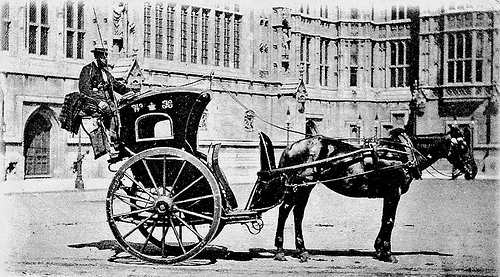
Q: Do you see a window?
A: Yes, there is a window.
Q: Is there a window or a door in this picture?
A: Yes, there is a window.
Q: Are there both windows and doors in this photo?
A: Yes, there are both a window and a door.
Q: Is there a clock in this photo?
A: No, there are no clocks.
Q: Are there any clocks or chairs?
A: No, there are no clocks or chairs.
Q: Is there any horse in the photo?
A: Yes, there is a horse.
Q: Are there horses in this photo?
A: Yes, there is a horse.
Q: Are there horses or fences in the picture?
A: Yes, there is a horse.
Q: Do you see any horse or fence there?
A: Yes, there is a horse.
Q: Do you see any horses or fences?
A: Yes, there is a horse.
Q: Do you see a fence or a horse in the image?
A: Yes, there is a horse.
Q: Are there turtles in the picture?
A: No, there are no turtles.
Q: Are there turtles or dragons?
A: No, there are no turtles or dragons.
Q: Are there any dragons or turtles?
A: No, there are no turtles or dragons.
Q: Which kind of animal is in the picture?
A: The animal is a horse.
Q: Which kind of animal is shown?
A: The animal is a horse.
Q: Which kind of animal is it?
A: The animal is a horse.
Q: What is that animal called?
A: This is a horse.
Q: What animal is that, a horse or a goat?
A: This is a horse.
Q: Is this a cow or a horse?
A: This is a horse.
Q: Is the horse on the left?
A: No, the horse is on the right of the image.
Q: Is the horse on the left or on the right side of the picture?
A: The horse is on the right of the image.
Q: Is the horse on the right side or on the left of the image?
A: The horse is on the right of the image.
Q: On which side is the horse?
A: The horse is on the right of the image.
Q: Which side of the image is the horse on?
A: The horse is on the right of the image.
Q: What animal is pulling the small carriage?
A: The horse is pulling the carriage.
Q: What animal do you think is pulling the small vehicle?
A: The horse is pulling the carriage.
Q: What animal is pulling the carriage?
A: The horse is pulling the carriage.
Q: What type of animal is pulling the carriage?
A: The animal is a horse.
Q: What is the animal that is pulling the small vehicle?
A: The animal is a horse.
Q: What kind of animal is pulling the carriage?
A: The animal is a horse.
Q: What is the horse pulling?
A: The horse is pulling the carriage.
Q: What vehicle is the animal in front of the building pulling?
A: The horse is pulling the carriage.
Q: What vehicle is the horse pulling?
A: The horse is pulling the carriage.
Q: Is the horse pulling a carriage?
A: Yes, the horse is pulling a carriage.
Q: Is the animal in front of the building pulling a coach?
A: No, the horse is pulling a carriage.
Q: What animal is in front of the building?
A: The horse is in front of the building.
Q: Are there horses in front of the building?
A: Yes, there is a horse in front of the building.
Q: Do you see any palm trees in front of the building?
A: No, there is a horse in front of the building.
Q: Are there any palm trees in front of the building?
A: No, there is a horse in front of the building.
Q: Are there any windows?
A: Yes, there is a window.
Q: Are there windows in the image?
A: Yes, there is a window.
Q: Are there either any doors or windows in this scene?
A: Yes, there is a window.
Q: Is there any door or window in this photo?
A: Yes, there is a window.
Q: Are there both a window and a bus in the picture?
A: No, there is a window but no buses.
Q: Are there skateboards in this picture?
A: No, there are no skateboards.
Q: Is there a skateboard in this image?
A: No, there are no skateboards.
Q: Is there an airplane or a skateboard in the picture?
A: No, there are no skateboards or airplanes.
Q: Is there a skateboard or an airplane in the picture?
A: No, there are no skateboards or airplanes.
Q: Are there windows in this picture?
A: Yes, there is a window.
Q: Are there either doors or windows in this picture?
A: Yes, there is a window.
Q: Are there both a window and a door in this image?
A: Yes, there are both a window and a door.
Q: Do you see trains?
A: No, there are no trains.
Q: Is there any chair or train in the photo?
A: No, there are no trains or chairs.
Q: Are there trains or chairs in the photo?
A: No, there are no trains or chairs.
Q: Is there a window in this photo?
A: Yes, there is a window.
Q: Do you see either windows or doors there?
A: Yes, there is a window.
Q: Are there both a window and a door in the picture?
A: Yes, there are both a window and a door.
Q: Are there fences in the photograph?
A: No, there are no fences.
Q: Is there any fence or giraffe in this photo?
A: No, there are no fences or giraffes.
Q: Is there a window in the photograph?
A: Yes, there is a window.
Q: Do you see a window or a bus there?
A: Yes, there is a window.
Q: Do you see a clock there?
A: No, there are no clocks.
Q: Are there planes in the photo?
A: No, there are no planes.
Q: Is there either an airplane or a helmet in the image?
A: No, there are no airplanes or helmets.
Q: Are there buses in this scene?
A: No, there are no buses.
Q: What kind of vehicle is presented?
A: The vehicle is a carriage.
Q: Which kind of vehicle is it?
A: The vehicle is a carriage.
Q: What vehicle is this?
A: This is a carriage.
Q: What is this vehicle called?
A: This is a carriage.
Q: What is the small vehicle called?
A: The vehicle is a carriage.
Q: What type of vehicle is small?
A: The vehicle is a carriage.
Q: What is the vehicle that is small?
A: The vehicle is a carriage.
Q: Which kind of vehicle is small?
A: The vehicle is a carriage.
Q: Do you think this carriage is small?
A: Yes, the carriage is small.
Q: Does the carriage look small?
A: Yes, the carriage is small.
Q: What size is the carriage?
A: The carriage is small.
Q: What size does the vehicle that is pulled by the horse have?
A: The carriage has small size.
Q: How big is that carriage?
A: The carriage is small.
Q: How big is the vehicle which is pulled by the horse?
A: The carriage is small.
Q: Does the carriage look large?
A: No, the carriage is small.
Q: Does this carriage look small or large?
A: The carriage is small.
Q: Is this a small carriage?
A: Yes, this is a small carriage.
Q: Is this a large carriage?
A: No, this is a small carriage.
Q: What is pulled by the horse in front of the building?
A: The carriage is pulled by the horse.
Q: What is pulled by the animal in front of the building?
A: The carriage is pulled by the horse.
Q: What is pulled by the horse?
A: The carriage is pulled by the horse.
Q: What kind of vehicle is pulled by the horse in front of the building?
A: The vehicle is a carriage.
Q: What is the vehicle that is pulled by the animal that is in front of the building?
A: The vehicle is a carriage.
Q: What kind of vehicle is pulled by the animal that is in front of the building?
A: The vehicle is a carriage.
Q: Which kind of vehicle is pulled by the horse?
A: The vehicle is a carriage.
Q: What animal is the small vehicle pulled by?
A: The carriage is pulled by the horse.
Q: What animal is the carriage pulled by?
A: The carriage is pulled by the horse.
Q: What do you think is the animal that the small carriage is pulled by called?
A: The animal is a horse.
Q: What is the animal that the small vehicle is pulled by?
A: The animal is a horse.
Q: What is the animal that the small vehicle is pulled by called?
A: The animal is a horse.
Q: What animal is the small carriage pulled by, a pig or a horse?
A: The carriage is pulled by a horse.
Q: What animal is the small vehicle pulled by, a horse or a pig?
A: The carriage is pulled by a horse.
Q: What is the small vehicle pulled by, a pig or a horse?
A: The carriage is pulled by a horse.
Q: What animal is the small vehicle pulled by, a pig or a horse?
A: The carriage is pulled by a horse.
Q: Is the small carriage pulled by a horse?
A: Yes, the carriage is pulled by a horse.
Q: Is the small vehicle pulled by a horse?
A: Yes, the carriage is pulled by a horse.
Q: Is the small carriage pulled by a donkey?
A: No, the carriage is pulled by a horse.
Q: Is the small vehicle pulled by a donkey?
A: No, the carriage is pulled by a horse.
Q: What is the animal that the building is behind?
A: The animal is a horse.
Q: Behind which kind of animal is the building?
A: The building is behind the horse.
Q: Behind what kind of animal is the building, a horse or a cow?
A: The building is behind a horse.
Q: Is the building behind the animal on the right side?
A: Yes, the building is behind the horse.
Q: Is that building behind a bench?
A: No, the building is behind the horse.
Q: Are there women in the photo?
A: No, there are no women.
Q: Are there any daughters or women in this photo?
A: No, there are no women or daughters.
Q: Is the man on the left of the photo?
A: Yes, the man is on the left of the image.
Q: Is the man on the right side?
A: No, the man is on the left of the image.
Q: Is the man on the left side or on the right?
A: The man is on the left of the image.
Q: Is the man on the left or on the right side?
A: The man is on the left of the image.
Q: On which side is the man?
A: The man is on the left of the image.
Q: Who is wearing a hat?
A: The man is wearing a hat.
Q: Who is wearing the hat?
A: The man is wearing a hat.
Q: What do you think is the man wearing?
A: The man is wearing a hat.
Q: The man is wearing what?
A: The man is wearing a hat.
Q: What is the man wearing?
A: The man is wearing a hat.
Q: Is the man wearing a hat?
A: Yes, the man is wearing a hat.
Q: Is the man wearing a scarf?
A: No, the man is wearing a hat.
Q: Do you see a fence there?
A: No, there are no fences.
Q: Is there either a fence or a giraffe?
A: No, there are no fences or giraffes.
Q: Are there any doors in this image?
A: Yes, there is a door.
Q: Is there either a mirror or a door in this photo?
A: Yes, there is a door.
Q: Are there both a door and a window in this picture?
A: Yes, there are both a door and a window.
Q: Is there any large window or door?
A: Yes, there is a large door.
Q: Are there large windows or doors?
A: Yes, there is a large door.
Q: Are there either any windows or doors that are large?
A: Yes, the door is large.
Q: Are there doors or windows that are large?
A: Yes, the door is large.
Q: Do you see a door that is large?
A: Yes, there is a large door.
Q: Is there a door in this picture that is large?
A: Yes, there is a door that is large.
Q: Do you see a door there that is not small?
A: Yes, there is a large door.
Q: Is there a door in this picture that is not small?
A: Yes, there is a large door.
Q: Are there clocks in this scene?
A: No, there are no clocks.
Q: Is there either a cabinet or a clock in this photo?
A: No, there are no clocks or cabinets.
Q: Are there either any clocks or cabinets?
A: No, there are no clocks or cabinets.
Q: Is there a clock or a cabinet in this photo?
A: No, there are no clocks or cabinets.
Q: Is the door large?
A: Yes, the door is large.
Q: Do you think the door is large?
A: Yes, the door is large.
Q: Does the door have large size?
A: Yes, the door is large.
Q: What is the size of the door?
A: The door is large.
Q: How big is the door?
A: The door is large.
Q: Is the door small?
A: No, the door is large.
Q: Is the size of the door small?
A: No, the door is large.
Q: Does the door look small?
A: No, the door is large.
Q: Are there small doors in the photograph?
A: No, there is a door but it is large.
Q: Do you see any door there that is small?
A: No, there is a door but it is large.